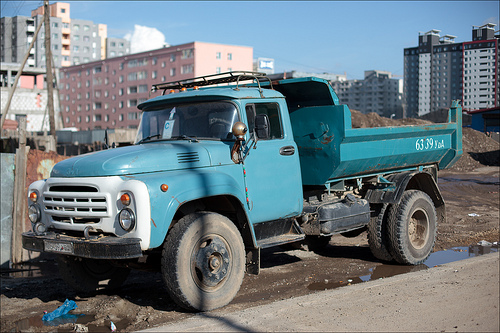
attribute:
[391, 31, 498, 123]
building — apartment, tall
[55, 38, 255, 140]
building — long, brick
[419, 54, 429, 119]
wall — white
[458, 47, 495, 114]
wall — white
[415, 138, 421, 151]
number — white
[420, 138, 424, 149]
number — white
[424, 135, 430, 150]
number — white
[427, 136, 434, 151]
number — white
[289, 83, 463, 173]
bed — blue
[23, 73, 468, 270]
truck — old, blue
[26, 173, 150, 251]
grill — white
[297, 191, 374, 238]
gas tank — black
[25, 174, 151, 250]
bumper — white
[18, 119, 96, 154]
fence — wood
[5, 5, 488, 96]
sky — blue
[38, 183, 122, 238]
grill — white, metal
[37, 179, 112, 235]
grill — white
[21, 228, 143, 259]
bumper — black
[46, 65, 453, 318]
parked tipper —  parked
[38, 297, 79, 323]
bag — blue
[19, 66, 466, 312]
truck — old, blue, loaded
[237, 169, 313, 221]
lorry — blue